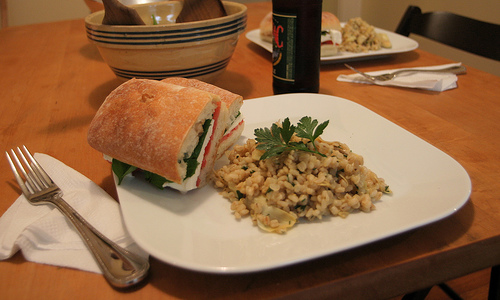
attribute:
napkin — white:
[2, 150, 149, 277]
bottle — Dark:
[261, 2, 334, 93]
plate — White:
[102, 82, 455, 269]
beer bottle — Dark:
[271, 0, 320, 95]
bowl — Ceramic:
[84, 24, 262, 96]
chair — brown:
[271, 5, 497, 297]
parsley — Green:
[254, 115, 329, 165]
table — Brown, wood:
[0, 19, 499, 297]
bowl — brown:
[69, 10, 254, 82]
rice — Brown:
[224, 118, 389, 232]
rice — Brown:
[215, 114, 382, 227]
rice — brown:
[218, 144, 369, 235]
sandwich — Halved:
[87, 75, 245, 193]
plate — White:
[110, 90, 475, 281]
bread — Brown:
[126, 101, 187, 164]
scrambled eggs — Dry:
[207, 115, 392, 232]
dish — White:
[109, 93, 471, 275]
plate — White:
[94, 81, 469, 279]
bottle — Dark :
[253, 3, 330, 97]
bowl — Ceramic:
[63, 0, 280, 73]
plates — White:
[248, 23, 431, 76]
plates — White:
[102, 87, 478, 278]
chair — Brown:
[397, 13, 498, 71]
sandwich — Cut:
[126, 65, 221, 188]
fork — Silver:
[1, 154, 143, 298]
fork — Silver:
[346, 56, 466, 86]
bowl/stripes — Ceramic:
[79, 3, 249, 81]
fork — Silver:
[3, 141, 151, 291]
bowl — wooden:
[84, 6, 251, 87]